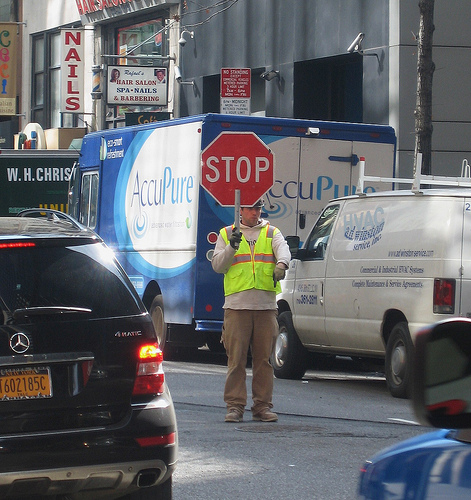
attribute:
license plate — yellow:
[0, 369, 54, 397]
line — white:
[388, 415, 420, 429]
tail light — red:
[425, 269, 459, 318]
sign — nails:
[57, 24, 87, 115]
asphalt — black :
[194, 428, 336, 489]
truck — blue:
[67, 111, 402, 360]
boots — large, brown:
[219, 400, 280, 426]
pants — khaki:
[204, 304, 357, 449]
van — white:
[260, 189, 470, 401]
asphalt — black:
[258, 444, 329, 456]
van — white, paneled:
[273, 160, 469, 410]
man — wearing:
[211, 201, 313, 433]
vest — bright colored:
[215, 220, 283, 291]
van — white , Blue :
[74, 127, 196, 231]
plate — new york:
[1, 366, 54, 395]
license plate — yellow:
[3, 358, 58, 409]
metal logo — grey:
[7, 327, 31, 360]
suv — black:
[0, 203, 178, 493]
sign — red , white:
[200, 129, 273, 247]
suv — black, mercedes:
[35, 267, 170, 438]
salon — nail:
[53, 34, 188, 122]